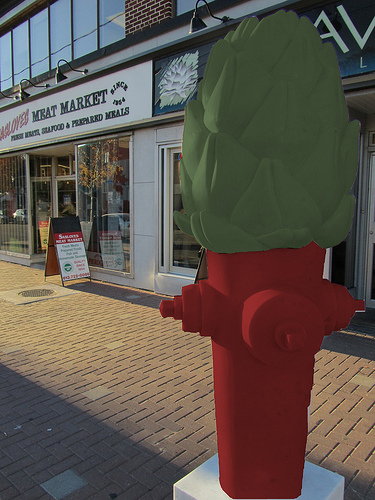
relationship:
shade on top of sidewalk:
[2, 362, 191, 499] [0, 259, 374, 499]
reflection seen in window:
[172, 152, 205, 270] [157, 142, 204, 279]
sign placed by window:
[42, 213, 93, 290] [74, 136, 131, 275]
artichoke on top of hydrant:
[170, 8, 364, 256] [157, 6, 365, 500]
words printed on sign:
[31, 86, 108, 124] [0, 60, 155, 155]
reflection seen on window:
[77, 135, 129, 275] [74, 136, 131, 275]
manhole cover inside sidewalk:
[18, 287, 56, 300] [0, 259, 374, 499]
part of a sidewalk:
[122, 289, 143, 303] [0, 259, 374, 499]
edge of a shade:
[1, 363, 188, 474] [2, 362, 191, 499]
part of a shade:
[66, 276, 124, 299] [65, 280, 374, 363]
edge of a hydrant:
[238, 247, 312, 499] [157, 6, 365, 500]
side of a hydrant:
[303, 242, 365, 494] [157, 6, 365, 500]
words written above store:
[31, 86, 108, 124] [0, 120, 151, 291]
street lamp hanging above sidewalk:
[13, 78, 51, 101] [0, 259, 374, 499]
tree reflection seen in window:
[174, 181, 203, 247] [157, 142, 204, 279]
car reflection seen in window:
[92, 211, 129, 247] [74, 136, 131, 275]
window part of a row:
[47, 1, 75, 71] [1, 1, 126, 95]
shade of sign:
[65, 280, 374, 363] [42, 213, 93, 290]